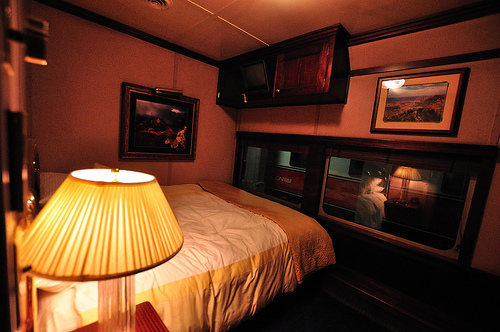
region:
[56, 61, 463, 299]
dark bedroom with lamp turned on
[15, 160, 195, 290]
pleated shade over glass pedestal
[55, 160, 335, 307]
comforter with wide hem in yellow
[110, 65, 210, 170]
dark picture hanging on wall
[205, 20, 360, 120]
dark cabinets hanging from ceiling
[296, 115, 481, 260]
screen reflecting lamp and bed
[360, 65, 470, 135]
artwork matted and framed in dark wood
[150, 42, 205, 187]
seam running down wall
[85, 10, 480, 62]
dark wood molding between ceiling and wall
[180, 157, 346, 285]
blanket folded at bottom of bed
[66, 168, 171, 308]
the lamp is on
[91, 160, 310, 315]
the bed is made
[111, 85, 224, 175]
painting on the wall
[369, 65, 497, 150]
picture on the wall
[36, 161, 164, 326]
lamp on side table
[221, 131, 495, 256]
there is reflection on the glass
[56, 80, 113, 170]
the wall is made of wood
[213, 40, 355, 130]
the cabinet is on the ceiling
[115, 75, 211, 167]
the frame is rectangle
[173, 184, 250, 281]
the blanket is white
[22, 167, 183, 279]
A yellow lamp shade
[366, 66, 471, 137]
A framed painting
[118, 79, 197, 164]
A framed painting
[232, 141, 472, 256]
Two windows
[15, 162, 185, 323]
An illuminated bedside lamo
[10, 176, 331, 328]
A white and yellow comforter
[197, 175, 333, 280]
An orange folded blanket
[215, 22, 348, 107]
Two hanging wooden cabinets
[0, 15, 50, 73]
A small wall lamp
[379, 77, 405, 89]
A reflection from the lamp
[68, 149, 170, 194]
light in lamp shade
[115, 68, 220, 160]
large picture on wall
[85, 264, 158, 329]
base of shade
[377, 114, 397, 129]
white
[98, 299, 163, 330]
dark brown night side table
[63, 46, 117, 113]
light pink walls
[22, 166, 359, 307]
large queen size bed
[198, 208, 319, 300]
patchwork quilt bed spread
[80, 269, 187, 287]
edge of tan lamp located on the night stand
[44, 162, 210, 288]
Lamp turned on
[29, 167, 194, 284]
Yellow lamp shade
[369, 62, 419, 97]
Reflection of lamp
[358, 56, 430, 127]
Reflection of lamp on picture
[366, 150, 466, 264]
Reflection of lamp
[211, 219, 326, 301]
Yellow and white bedspread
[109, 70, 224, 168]
Picture hanging on wall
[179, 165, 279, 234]
Yellow blanket on bed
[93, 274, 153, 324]
Clear base of lamp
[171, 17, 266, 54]
Ceiling of room in bed room